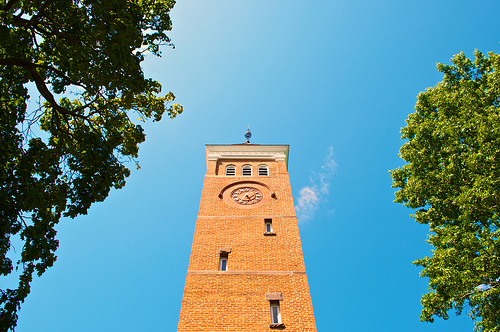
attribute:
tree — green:
[388, 47, 499, 329]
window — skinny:
[261, 215, 278, 240]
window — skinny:
[216, 245, 233, 274]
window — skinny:
[262, 290, 294, 327]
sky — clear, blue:
[1, 2, 498, 329]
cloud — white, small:
[291, 146, 341, 224]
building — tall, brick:
[183, 130, 320, 330]